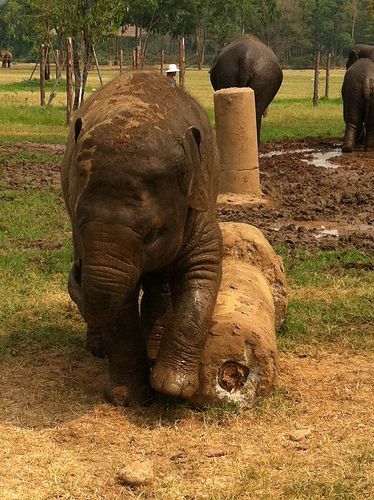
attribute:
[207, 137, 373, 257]
mud — brown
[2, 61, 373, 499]
ground — grassy, the ground 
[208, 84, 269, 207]
pillar — stone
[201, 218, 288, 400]
pillar — overturned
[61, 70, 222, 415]
elephant — young, brown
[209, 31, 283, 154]
elephant — adult, large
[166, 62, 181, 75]
hat — white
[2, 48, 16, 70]
elephant — large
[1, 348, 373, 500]
grass — brown